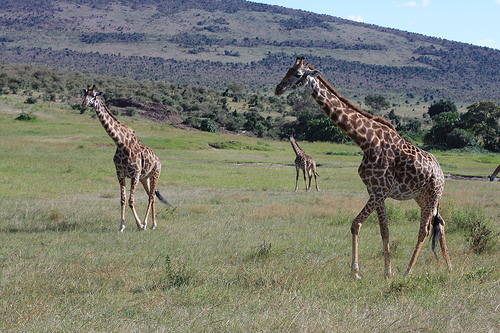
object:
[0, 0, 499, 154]
hill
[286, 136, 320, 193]
giraffe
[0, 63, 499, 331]
plain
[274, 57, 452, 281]
giraffe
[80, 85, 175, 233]
giraffe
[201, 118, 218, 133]
green bushes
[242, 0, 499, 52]
sky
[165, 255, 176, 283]
grass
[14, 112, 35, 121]
bushes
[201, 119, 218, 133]
bushes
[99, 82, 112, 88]
bushes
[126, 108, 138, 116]
bushes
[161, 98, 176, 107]
bushes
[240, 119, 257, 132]
bushes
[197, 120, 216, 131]
bushes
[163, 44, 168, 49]
bushes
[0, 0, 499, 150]
hill side